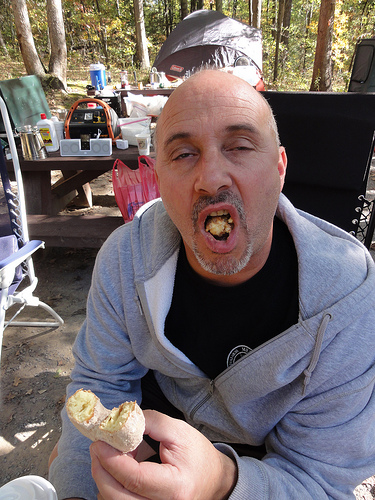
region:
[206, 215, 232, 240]
a piece of donut in mouth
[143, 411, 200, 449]
left thumb of person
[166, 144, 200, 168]
right eye of man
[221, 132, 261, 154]
left eye of man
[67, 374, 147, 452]
a bitten donut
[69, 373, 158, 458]
donut in man's hand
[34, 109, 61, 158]
bottle of lighter fluid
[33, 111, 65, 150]
white bottle with red cap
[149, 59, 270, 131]
a bald head of man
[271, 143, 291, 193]
left ear of man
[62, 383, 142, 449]
white powdered sugar doughnut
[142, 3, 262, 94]
gray tent in between trees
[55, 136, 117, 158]
white speakers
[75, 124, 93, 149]
music playing device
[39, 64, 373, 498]
man wearing gray jacket eating doughnut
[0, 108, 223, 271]
wooden picnic table in woods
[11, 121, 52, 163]
silver metal tea kettle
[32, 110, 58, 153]
white plastic bottle with yellow label and red cap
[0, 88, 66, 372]
white metal outdoor chair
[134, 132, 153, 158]
white and brown disposable coffee cup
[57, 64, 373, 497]
man with his mouth open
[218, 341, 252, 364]
white logo on black shirt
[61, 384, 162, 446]
partially eaten donut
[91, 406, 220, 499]
hand holding partially eaten donut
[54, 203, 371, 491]
gray jacket of man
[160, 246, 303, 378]
black shirt of man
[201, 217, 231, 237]
chewed donut in man's mouth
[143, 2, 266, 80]
tent surrounded by trees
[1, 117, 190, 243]
picnic table behind man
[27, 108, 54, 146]
white bottle with red cap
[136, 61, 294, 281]
A man with food in his mouth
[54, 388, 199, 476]
A man with donut in his hand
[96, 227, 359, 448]
A gray hooded sweatshirt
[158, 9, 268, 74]
A canvas cover/tent behind man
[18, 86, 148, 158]
Several items on table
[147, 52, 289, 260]
A man with his mouth open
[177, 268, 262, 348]
A black tee shirt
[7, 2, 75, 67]
A tree with double trunk on left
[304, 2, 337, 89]
A large tree trunk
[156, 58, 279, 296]
A man with a mustache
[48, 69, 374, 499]
A man eating a donut.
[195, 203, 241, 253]
The man's mouth is open revealing the half eaten food within.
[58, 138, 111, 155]
An ipod speaker system.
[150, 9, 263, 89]
A gray camping tent.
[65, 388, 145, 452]
A partially eaten donut.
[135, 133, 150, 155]
A styrofoam coffee cup.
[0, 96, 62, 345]
A lawn chair with a white metal base.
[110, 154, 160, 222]
A red plastic grocery bag.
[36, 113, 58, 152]
A white plastic bottle with a red cap.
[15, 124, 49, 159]
A silver metal coffee pot.